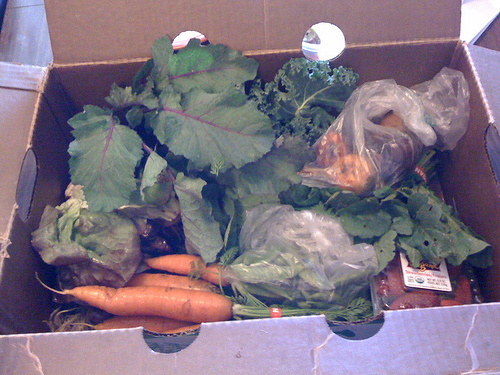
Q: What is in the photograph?
A: Vegetables.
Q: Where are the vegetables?
A: In a box.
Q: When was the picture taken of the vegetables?
A: Daytime.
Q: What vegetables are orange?
A: Carrots.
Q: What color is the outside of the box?
A: White.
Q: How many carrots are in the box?
A: Four.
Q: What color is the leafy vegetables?
A: Green.